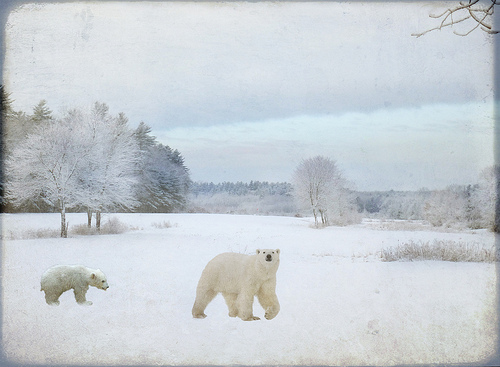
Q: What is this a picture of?
A: Two polar bears.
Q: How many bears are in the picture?
A: Two.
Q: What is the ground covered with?
A: Snow.